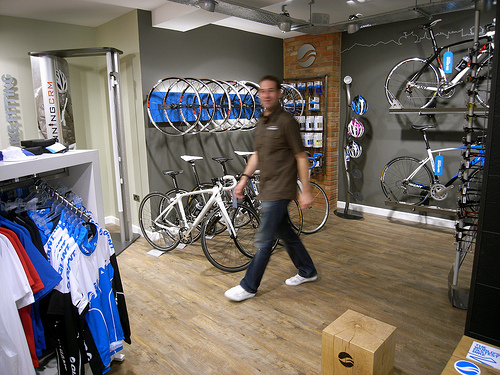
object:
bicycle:
[135, 168, 261, 271]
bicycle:
[384, 15, 496, 109]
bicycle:
[378, 124, 489, 207]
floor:
[78, 210, 498, 374]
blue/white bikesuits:
[42, 205, 134, 365]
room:
[2, 3, 497, 375]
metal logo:
[279, 45, 325, 182]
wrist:
[240, 176, 249, 182]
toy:
[343, 90, 367, 166]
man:
[223, 73, 319, 302]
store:
[2, 4, 490, 375]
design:
[337, 7, 494, 51]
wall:
[0, 12, 492, 229]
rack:
[26, 44, 120, 154]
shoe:
[222, 283, 257, 302]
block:
[321, 309, 399, 375]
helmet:
[346, 117, 365, 139]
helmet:
[345, 140, 363, 158]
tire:
[378, 154, 433, 210]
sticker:
[452, 359, 482, 375]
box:
[440, 333, 497, 375]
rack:
[32, 181, 96, 232]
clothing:
[0, 184, 131, 375]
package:
[432, 333, 499, 375]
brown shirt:
[250, 110, 307, 202]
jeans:
[238, 200, 318, 294]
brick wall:
[282, 35, 341, 202]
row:
[139, 76, 298, 139]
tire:
[145, 75, 201, 135]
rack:
[148, 91, 260, 118]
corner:
[282, 34, 337, 207]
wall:
[282, 29, 340, 213]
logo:
[337, 351, 352, 369]